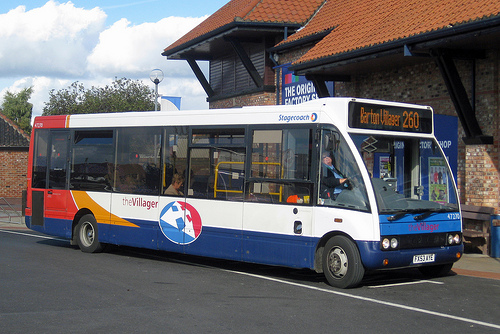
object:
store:
[159, 0, 498, 276]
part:
[367, 69, 424, 96]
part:
[155, 70, 162, 80]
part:
[171, 140, 181, 156]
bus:
[21, 96, 465, 290]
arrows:
[158, 199, 204, 245]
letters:
[409, 222, 440, 233]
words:
[360, 107, 421, 129]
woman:
[164, 171, 185, 196]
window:
[160, 127, 186, 197]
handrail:
[213, 161, 284, 203]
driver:
[319, 151, 352, 201]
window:
[310, 123, 372, 214]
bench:
[461, 203, 497, 255]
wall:
[334, 50, 500, 254]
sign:
[281, 63, 319, 107]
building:
[161, 0, 500, 110]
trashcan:
[487, 215, 498, 259]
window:
[345, 131, 461, 215]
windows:
[32, 127, 161, 200]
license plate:
[412, 253, 436, 264]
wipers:
[387, 207, 444, 221]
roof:
[162, 0, 500, 66]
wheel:
[76, 214, 104, 253]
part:
[86, 228, 98, 252]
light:
[148, 68, 164, 112]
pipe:
[271, 55, 280, 105]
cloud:
[0, 0, 213, 103]